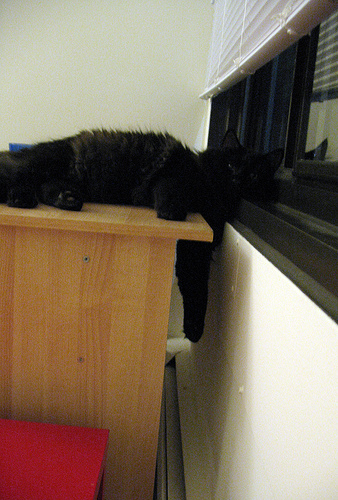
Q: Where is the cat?
A: On desk.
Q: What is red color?
A: Table top.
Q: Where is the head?
A: Cat.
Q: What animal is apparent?
A: A cat.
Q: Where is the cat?
A: Lying on a desk.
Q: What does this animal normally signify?
A: Bad luck.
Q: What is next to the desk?
A: A red table.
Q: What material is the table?
A: Wood.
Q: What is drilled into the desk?
A: Screws.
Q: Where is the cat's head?
A: On the window ledge.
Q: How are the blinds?
A: Half drawn.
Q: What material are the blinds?
A: Plastic.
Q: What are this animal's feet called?
A: Paws.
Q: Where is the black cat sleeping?
A: On dresser.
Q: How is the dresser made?
A: Wood.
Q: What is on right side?
A: White wall.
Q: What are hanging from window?
A: White blinds.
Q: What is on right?
A: Glass window.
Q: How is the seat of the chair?
A: Red.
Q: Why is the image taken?
A: Remembrance.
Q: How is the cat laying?
A: Paw stretched.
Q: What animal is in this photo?
A: A cat.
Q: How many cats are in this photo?
A: One.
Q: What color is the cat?
A: Black.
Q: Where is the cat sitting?
A: On a table top.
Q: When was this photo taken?
A: Night time.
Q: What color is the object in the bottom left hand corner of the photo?
A: Red.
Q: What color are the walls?
A: White.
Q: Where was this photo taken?
A: In someone's home.